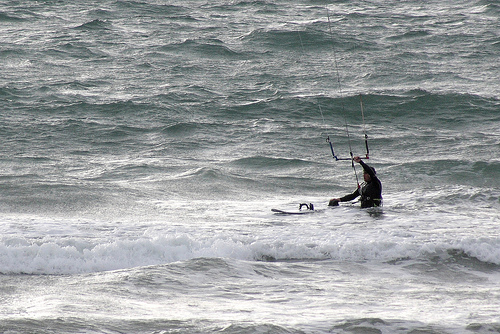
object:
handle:
[327, 198, 339, 206]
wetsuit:
[339, 160, 383, 209]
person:
[330, 156, 383, 208]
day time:
[0, 1, 499, 333]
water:
[0, 0, 500, 334]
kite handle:
[325, 134, 370, 161]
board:
[271, 197, 340, 214]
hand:
[329, 197, 339, 203]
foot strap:
[298, 202, 313, 211]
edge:
[270, 207, 281, 214]